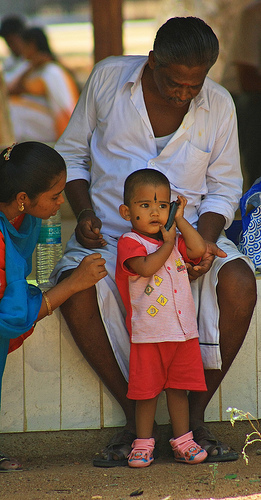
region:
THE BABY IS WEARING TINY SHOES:
[121, 422, 215, 486]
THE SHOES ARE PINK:
[121, 425, 210, 476]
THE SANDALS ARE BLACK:
[79, 412, 243, 468]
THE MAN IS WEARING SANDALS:
[68, 401, 246, 480]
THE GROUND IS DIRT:
[2, 440, 260, 498]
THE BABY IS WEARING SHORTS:
[110, 333, 208, 413]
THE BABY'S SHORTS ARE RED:
[111, 329, 212, 412]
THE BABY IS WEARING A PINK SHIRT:
[87, 220, 210, 369]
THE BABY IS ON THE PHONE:
[156, 195, 183, 240]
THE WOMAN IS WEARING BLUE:
[0, 204, 56, 380]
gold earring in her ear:
[15, 202, 25, 211]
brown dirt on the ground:
[0, 418, 258, 499]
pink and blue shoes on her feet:
[125, 429, 207, 467]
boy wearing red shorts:
[125, 334, 211, 399]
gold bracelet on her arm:
[39, 287, 53, 313]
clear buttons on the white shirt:
[147, 133, 157, 167]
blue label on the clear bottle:
[37, 222, 63, 244]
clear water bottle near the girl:
[33, 206, 63, 288]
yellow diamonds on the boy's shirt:
[145, 271, 168, 319]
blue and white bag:
[239, 174, 260, 269]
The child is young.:
[114, 164, 202, 411]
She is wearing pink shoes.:
[132, 432, 204, 472]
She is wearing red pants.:
[124, 339, 205, 400]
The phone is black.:
[165, 201, 181, 237]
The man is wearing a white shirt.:
[66, 57, 236, 252]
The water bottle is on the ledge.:
[35, 207, 64, 289]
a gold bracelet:
[38, 288, 55, 318]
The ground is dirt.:
[6, 429, 259, 499]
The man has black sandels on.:
[95, 417, 236, 463]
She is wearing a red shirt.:
[111, 233, 202, 341]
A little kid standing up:
[110, 168, 214, 470]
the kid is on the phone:
[111, 170, 208, 462]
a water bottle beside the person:
[34, 205, 65, 280]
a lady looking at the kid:
[0, 136, 108, 486]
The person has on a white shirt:
[50, 17, 252, 491]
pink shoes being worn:
[121, 432, 211, 465]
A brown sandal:
[93, 423, 131, 470]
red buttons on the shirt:
[163, 262, 186, 319]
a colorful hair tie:
[3, 140, 16, 164]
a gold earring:
[17, 203, 27, 212]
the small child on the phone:
[115, 168, 207, 466]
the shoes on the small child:
[126, 430, 206, 465]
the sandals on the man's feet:
[91, 423, 239, 467]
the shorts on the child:
[125, 340, 207, 399]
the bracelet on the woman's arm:
[41, 290, 52, 315]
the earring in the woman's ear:
[18, 202, 24, 211]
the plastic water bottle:
[35, 206, 61, 287]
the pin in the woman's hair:
[4, 141, 17, 160]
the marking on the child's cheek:
[135, 214, 139, 221]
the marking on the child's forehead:
[153, 190, 157, 204]